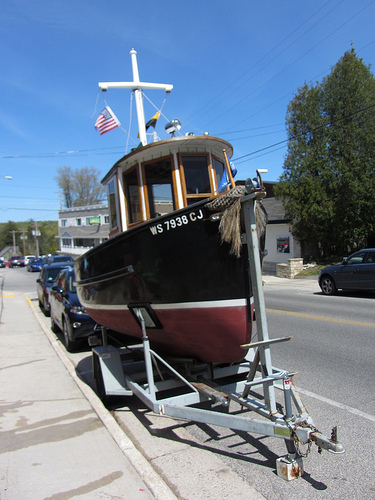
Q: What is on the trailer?
A: Boat.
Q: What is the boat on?
A: Grey trailer.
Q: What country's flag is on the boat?
A: USA.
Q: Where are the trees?
A: Alongside the road.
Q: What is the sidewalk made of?
A: Concrete.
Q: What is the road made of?
A: Asphalt.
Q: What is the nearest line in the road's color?
A: White.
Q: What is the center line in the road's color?
A: Yellow.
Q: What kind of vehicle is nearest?
A: A boat.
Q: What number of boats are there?
A: One.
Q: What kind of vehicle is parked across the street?
A: A car.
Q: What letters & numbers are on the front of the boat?
A: WS 7938 CJ.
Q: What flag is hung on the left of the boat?
A: American flag.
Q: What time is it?
A: Afternoon.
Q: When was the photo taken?
A: During the daytime.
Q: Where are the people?
A: None in photo.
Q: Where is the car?
A: On the road.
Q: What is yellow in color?
A: The line on the road.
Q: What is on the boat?
A: A flag.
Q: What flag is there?
A: American.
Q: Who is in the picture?
A: No one.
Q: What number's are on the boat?
A: 7938.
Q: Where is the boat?
A: On the street.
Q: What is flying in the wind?
A: Flags.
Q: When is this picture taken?
A: Daytime.